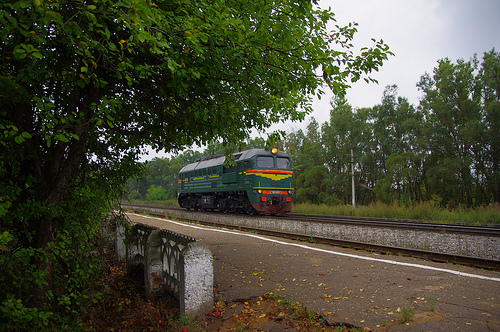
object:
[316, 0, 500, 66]
sky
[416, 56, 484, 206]
tree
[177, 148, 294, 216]
locomotive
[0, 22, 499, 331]
countryside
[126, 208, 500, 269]
track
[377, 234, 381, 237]
rocks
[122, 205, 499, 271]
railroad tracks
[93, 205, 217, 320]
fence